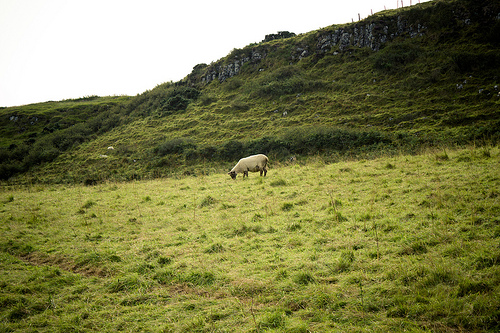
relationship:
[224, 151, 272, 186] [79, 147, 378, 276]
sheep in field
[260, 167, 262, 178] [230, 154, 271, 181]
legs of animal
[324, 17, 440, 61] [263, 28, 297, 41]
cliff. on tree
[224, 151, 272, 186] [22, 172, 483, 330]
sheep in grass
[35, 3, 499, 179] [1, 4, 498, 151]
grass on hillside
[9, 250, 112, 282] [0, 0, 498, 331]
dirt in grass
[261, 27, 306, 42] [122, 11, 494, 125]
bush on top of hill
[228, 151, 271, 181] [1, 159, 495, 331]
lamb in field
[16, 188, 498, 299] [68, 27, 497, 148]
field under hillside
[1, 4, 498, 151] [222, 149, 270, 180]
hillside above sheep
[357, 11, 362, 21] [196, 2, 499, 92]
post on top of cliff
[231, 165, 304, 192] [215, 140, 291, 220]
legs of sheep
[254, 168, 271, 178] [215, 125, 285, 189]
legs of sheep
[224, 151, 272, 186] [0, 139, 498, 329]
sheep grazing on grass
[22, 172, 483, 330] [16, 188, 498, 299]
grass covered field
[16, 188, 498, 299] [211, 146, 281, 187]
field with sheep